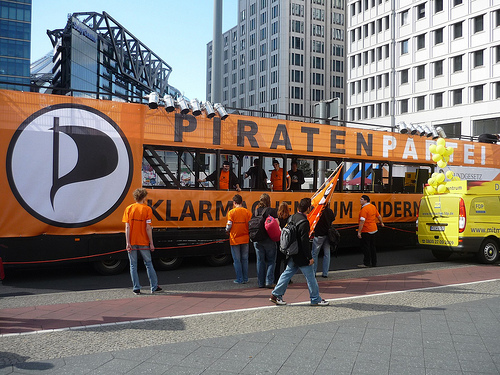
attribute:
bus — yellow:
[417, 178, 499, 261]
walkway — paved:
[242, 331, 462, 345]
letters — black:
[169, 111, 374, 162]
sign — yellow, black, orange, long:
[1, 77, 499, 246]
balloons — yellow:
[419, 132, 461, 196]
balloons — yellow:
[427, 137, 454, 168]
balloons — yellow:
[426, 171, 447, 193]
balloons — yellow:
[447, 170, 462, 181]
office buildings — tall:
[344, 1, 499, 150]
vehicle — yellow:
[391, 151, 498, 251]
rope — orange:
[15, 241, 225, 266]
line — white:
[144, 307, 208, 324]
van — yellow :
[287, 145, 494, 230]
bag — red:
[257, 210, 290, 247]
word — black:
[167, 108, 376, 162]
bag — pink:
[266, 215, 281, 240]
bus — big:
[1, 93, 499, 254]